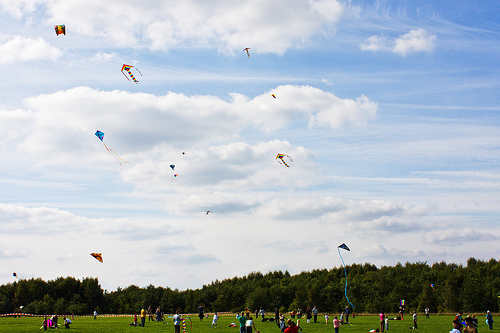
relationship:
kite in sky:
[93, 129, 129, 169] [1, 2, 477, 246]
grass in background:
[0, 312, 500, 333] [5, 301, 435, 321]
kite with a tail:
[93, 127, 105, 142] [101, 140, 122, 166]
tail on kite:
[335, 249, 356, 307] [335, 241, 350, 252]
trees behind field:
[213, 260, 436, 311] [14, 310, 465, 330]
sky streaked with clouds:
[317, 2, 483, 177] [61, 80, 341, 190]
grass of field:
[0, 312, 500, 333] [3, 310, 413, 331]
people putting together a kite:
[34, 313, 74, 331] [44, 319, 55, 329]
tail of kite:
[100, 140, 125, 171] [93, 130, 108, 142]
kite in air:
[54, 20, 66, 37] [9, 6, 413, 221]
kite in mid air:
[89, 127, 118, 157] [16, 42, 461, 214]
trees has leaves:
[440, 274, 459, 313] [2, 252, 498, 308]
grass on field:
[0, 312, 500, 333] [10, 308, 499, 328]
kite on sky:
[93, 129, 129, 169] [2, 3, 498, 263]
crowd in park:
[1, 303, 499, 332] [4, 304, 498, 329]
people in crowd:
[10, 303, 499, 332] [1, 303, 499, 332]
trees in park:
[2, 255, 498, 313] [2, 301, 498, 331]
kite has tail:
[272, 146, 293, 171] [277, 154, 293, 172]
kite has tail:
[335, 237, 351, 251] [333, 248, 345, 266]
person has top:
[235, 304, 256, 325] [237, 315, 251, 327]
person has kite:
[208, 308, 220, 328] [92, 124, 110, 154]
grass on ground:
[8, 310, 498, 328] [4, 310, 496, 331]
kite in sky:
[93, 129, 129, 169] [2, 3, 498, 263]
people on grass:
[262, 303, 356, 326] [128, 308, 428, 329]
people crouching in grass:
[58, 314, 74, 327] [0, 312, 500, 333]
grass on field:
[0, 312, 500, 333] [0, 314, 499, 332]